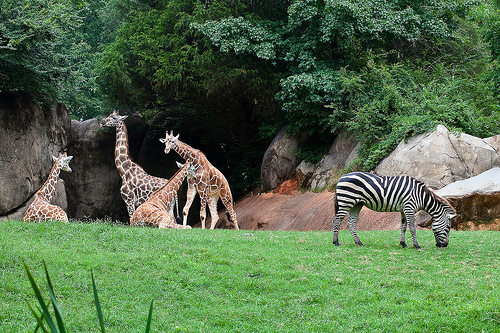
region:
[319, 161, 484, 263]
the zebra is eating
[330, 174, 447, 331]
the zebra is eating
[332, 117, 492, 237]
the zebra is eating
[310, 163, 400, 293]
the zebra is eating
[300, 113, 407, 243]
the zebra is eating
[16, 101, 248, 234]
four giraffes in a zoo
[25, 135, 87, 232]
giraffe sits on green grass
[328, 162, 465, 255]
a zebra is eating grass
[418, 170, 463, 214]
mane of zebra is short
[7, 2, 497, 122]
trees have different color of gree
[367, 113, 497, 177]
big rock on right side of pen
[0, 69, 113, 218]
large rocks on left of pen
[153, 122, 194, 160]
giraffe has two horns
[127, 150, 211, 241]
a giraffe sits in the grass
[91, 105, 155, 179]
giraffe has big neck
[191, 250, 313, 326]
The grass is green.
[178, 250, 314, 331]
The grass is lush.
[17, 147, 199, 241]
Two giraffes are sitting.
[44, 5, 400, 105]
The trees are green.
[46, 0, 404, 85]
Trees are in the background.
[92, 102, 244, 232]
Two giraffes are standing.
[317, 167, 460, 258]
A zebra is in the picture.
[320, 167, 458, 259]
The zebra is black and white.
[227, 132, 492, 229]
Rocks are in the background.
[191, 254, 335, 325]
The grass is thick.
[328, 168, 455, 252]
black and white zebra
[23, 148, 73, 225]
giraffe sitting next to wall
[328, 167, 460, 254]
zebra eating green grass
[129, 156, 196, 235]
giraffe eating green grass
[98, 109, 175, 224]
giraffe looking for food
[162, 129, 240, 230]
giraffe walking on grass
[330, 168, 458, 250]
zebra standing in grass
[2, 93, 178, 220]
grey rock barrier wall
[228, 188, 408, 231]
pile of brown dirt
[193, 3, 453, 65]
branches with green leaves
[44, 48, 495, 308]
animals grazing on field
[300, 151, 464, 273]
zebra grazing on field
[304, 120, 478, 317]
bent over zebra eating grass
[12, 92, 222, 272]
giraffes hanging out on field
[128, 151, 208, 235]
giraffe laying on the ground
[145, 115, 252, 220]
giraffe standing on grass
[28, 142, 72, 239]
another giraffe laying on grass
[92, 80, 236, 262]
three giraffes on the grass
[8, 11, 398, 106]
large bushy green trees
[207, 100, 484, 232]
huge rock structure behind zebra